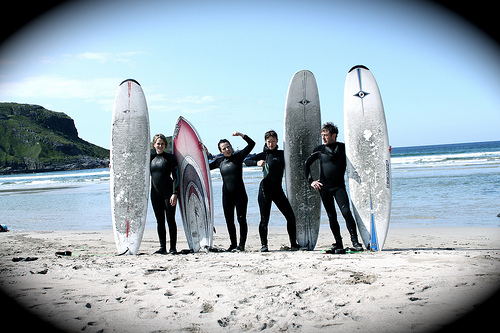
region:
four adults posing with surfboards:
[110, 115, 383, 267]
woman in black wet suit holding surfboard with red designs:
[177, 115, 249, 257]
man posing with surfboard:
[302, 98, 385, 258]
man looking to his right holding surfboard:
[301, 122, 348, 254]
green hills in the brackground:
[11, 102, 105, 190]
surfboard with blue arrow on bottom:
[364, 183, 390, 253]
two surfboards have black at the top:
[109, 60, 387, 90]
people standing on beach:
[60, 32, 455, 279]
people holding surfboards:
[66, 38, 413, 290]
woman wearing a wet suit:
[200, 130, 262, 236]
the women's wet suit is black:
[208, 130, 267, 236]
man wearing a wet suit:
[300, 133, 370, 258]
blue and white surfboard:
[316, 58, 410, 258]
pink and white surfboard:
[155, 94, 233, 274]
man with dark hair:
[317, 107, 348, 144]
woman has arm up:
[225, 125, 253, 159]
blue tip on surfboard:
[105, 62, 151, 99]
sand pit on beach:
[194, 297, 216, 317]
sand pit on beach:
[234, 293, 263, 313]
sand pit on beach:
[263, 304, 283, 324]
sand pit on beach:
[294, 281, 315, 305]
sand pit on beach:
[349, 264, 371, 296]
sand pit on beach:
[294, 308, 320, 325]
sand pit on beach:
[404, 286, 429, 311]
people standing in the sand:
[106, 77, 413, 250]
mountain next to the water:
[1, 88, 110, 201]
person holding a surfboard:
[311, 63, 400, 268]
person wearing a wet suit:
[134, 126, 213, 284]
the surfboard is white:
[341, 63, 396, 239]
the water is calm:
[407, 133, 484, 268]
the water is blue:
[411, 114, 482, 235]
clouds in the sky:
[28, 40, 124, 126]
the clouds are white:
[31, 56, 136, 143]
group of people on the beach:
[107, 49, 407, 258]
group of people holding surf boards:
[91, 53, 394, 273]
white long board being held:
[102, 79, 154, 260]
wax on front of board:
[115, 115, 142, 215]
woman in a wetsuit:
[145, 128, 178, 265]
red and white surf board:
[168, 116, 220, 263]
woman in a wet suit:
[195, 135, 255, 260]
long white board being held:
[287, 67, 324, 252]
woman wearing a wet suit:
[245, 124, 295, 254]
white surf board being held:
[339, 58, 399, 256]